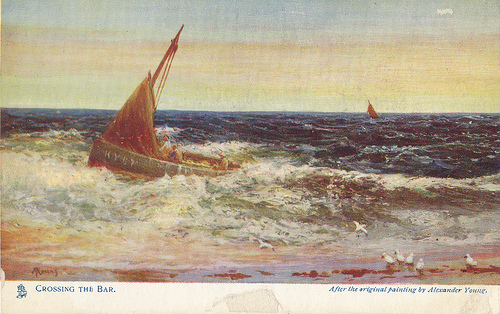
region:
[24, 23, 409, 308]
this is a painting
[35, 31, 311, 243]
this is an art piece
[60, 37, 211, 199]
this is a sail boat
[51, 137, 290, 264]
the boat is in waves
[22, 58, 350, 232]
the boat is in a storm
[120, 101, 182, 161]
the sail is brown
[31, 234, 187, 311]
this is a beach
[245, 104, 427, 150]
this is the ocean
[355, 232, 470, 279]
these are seagulls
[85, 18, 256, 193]
an old time sail boat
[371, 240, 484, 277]
seagulls on the beach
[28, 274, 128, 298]
text that reads crossing the bar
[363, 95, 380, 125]
a sail boat in the distance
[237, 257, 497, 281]
rocks on the beach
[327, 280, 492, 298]
text the reads after the original painting by alexander young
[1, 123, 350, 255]
white waves crashing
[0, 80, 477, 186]
a large body of water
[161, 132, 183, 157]
people in a boat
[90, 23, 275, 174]
boar in the water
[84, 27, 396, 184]
two boat in the water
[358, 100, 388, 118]
boat near the horizon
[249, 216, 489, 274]
birds on the waters edge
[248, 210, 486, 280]
white seagulls by the water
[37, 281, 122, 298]
title of the picture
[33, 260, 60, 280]
signature of the artist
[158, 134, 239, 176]
people aboard the boat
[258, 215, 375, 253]
two seagulls in the air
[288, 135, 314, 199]
part of a cloud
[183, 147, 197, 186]
edge of a boat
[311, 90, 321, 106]
part of a cloud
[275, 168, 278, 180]
part of an ocean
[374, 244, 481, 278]
Birds on the beach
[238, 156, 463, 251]
waves in the ocean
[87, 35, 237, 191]
sailboat on the water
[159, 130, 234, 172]
people sitting in a sailboat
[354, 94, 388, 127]
Boat in the middle of the ocean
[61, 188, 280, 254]
water washing up a shore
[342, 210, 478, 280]
bird on the water edge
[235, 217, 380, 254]
birds flying over the water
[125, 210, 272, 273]
water washing up ashore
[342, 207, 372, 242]
Birds flying over the water